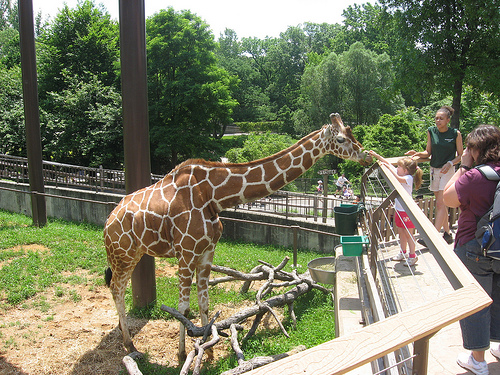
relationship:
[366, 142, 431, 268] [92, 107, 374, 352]
girl petting giraffe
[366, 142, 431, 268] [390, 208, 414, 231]
girl wearing red shorts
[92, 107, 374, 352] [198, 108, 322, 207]
giraffe has a long neck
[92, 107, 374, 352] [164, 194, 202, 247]
giraffe has brown spots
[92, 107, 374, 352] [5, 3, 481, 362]
giraffe in a zoo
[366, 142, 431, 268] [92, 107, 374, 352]
girl feeding a giraffe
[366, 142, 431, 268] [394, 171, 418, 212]
girl wearing white shirt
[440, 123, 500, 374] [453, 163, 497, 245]
lady wearing a purple shirt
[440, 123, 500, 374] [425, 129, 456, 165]
lady wearing a green shirt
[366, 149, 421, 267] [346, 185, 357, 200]
girl pushing a stroller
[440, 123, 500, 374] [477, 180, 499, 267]
lady wearing a backpack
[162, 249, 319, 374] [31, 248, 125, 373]
branches on ground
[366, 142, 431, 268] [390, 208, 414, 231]
girl in red shorts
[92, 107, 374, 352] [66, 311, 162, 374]
giraffe in dirt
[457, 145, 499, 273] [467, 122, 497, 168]
lady has a big hairdo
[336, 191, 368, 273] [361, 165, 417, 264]
feed container on ledge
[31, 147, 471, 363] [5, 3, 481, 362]
cage in zoo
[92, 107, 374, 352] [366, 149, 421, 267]
giraffe bending toward girl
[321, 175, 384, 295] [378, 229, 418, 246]
buckets on gate